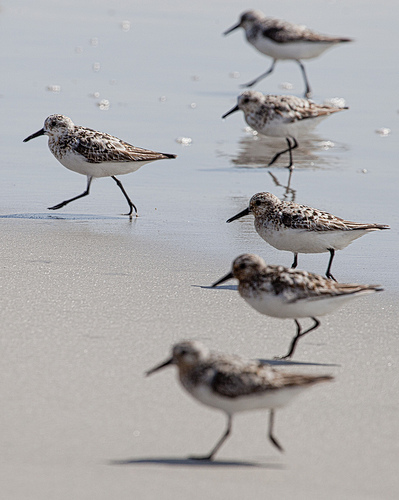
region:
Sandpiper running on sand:
[17, 113, 177, 218]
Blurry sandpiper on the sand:
[137, 339, 335, 463]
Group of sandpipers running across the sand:
[15, 8, 389, 462]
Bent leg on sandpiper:
[46, 172, 96, 213]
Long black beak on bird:
[225, 208, 248, 222]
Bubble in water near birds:
[175, 136, 193, 146]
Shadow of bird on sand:
[112, 450, 256, 469]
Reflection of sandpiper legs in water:
[265, 167, 299, 195]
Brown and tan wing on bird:
[197, 359, 298, 393]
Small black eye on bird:
[49, 119, 56, 126]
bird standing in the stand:
[22, 90, 176, 225]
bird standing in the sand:
[148, 327, 341, 463]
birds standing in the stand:
[213, 252, 377, 352]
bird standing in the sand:
[228, 172, 388, 264]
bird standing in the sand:
[222, 74, 360, 169]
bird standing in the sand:
[222, 3, 349, 89]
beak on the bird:
[13, 114, 43, 149]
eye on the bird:
[46, 118, 57, 131]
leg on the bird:
[107, 171, 144, 229]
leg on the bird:
[46, 159, 94, 219]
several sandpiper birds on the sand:
[19, 9, 395, 474]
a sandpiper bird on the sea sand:
[15, 103, 185, 238]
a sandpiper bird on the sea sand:
[206, 7, 363, 85]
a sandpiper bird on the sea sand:
[212, 75, 363, 163]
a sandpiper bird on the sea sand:
[217, 174, 387, 250]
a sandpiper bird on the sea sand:
[200, 243, 388, 350]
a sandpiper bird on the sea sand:
[119, 331, 337, 484]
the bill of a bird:
[18, 121, 44, 158]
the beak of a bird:
[13, 118, 44, 152]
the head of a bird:
[17, 103, 76, 151]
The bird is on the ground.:
[207, 9, 364, 99]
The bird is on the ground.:
[216, 84, 356, 178]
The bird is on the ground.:
[211, 189, 395, 281]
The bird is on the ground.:
[197, 253, 394, 361]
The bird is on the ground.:
[19, 109, 182, 226]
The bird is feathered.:
[136, 333, 346, 472]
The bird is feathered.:
[208, 251, 389, 359]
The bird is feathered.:
[208, 5, 367, 96]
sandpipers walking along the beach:
[15, 17, 359, 433]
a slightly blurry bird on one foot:
[141, 358, 304, 476]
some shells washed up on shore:
[90, 55, 223, 132]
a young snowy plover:
[16, 114, 168, 220]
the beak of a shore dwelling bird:
[222, 198, 253, 231]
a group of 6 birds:
[21, 32, 362, 494]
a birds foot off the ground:
[250, 411, 291, 452]